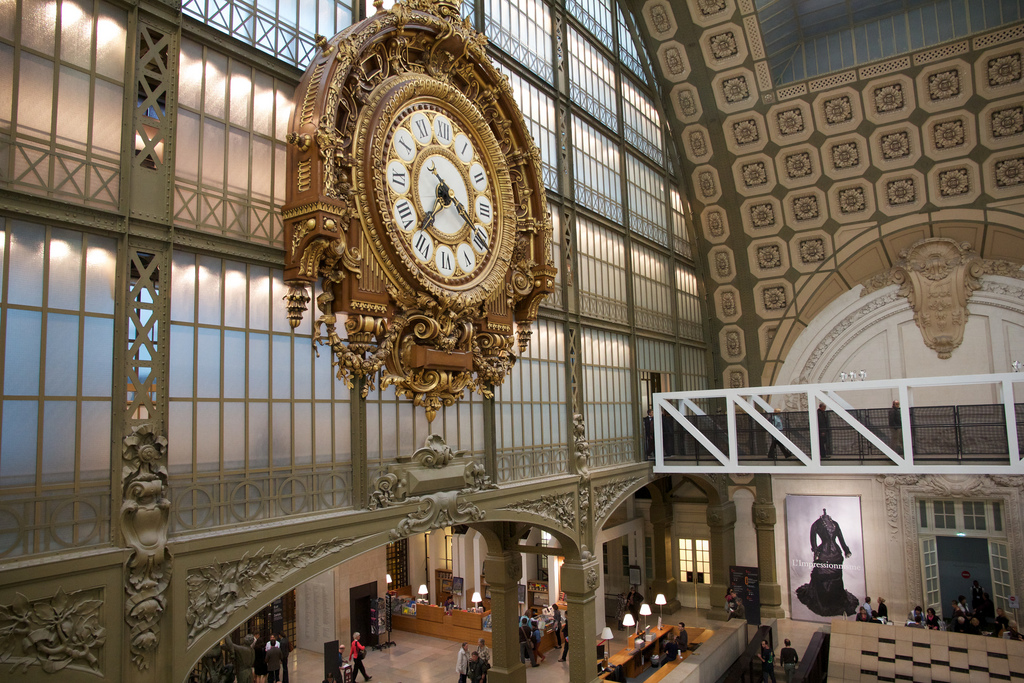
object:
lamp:
[417, 585, 428, 594]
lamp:
[471, 592, 482, 603]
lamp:
[600, 627, 614, 659]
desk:
[595, 624, 678, 682]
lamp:
[622, 614, 635, 647]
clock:
[280, 0, 548, 406]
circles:
[383, 130, 416, 235]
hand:
[447, 194, 494, 253]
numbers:
[381, 110, 494, 278]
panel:
[0, 0, 701, 478]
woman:
[340, 632, 375, 682]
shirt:
[348, 639, 365, 659]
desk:
[389, 603, 493, 647]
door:
[909, 494, 1016, 637]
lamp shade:
[600, 594, 668, 663]